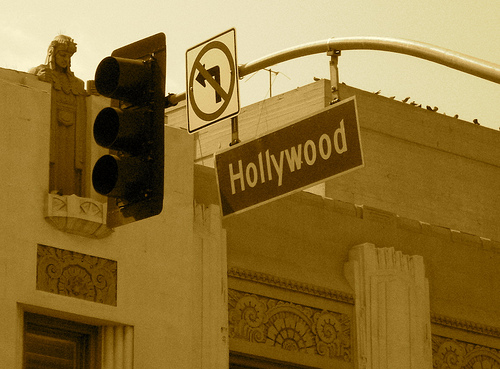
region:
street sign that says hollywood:
[187, 122, 449, 245]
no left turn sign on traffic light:
[160, 31, 287, 149]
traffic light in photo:
[74, 34, 234, 278]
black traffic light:
[79, 33, 264, 268]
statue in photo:
[39, 39, 111, 246]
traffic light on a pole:
[79, 46, 493, 204]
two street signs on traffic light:
[174, 42, 396, 242]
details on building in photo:
[200, 264, 467, 366]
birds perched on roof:
[306, 49, 497, 167]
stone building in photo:
[7, 67, 358, 364]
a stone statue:
[32, 22, 94, 212]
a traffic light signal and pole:
[87, 17, 497, 258]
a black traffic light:
[85, 25, 180, 240]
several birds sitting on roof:
[310, 65, 482, 128]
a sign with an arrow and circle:
[178, 22, 249, 135]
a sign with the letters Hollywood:
[209, 93, 370, 229]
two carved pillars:
[182, 189, 462, 367]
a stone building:
[0, 64, 497, 366]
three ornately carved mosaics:
[22, 225, 497, 367]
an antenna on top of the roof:
[243, 57, 292, 103]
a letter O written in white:
[245, 160, 257, 188]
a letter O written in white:
[301, 137, 317, 162]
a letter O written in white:
[318, 131, 333, 165]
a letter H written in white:
[224, 157, 246, 194]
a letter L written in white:
[256, 151, 265, 184]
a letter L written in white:
[263, 145, 273, 182]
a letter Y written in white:
[270, 147, 287, 184]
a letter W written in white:
[283, 142, 303, 170]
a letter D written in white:
[331, 115, 350, 152]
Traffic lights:
[91, 50, 146, 199]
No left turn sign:
[185, 26, 241, 133]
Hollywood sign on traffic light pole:
[206, 92, 361, 217]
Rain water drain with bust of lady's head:
[25, 31, 90, 226]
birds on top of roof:
[335, 66, 485, 126]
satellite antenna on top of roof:
[250, 65, 285, 95]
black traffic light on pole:
[91, 28, 165, 231]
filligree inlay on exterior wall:
[34, 239, 121, 307]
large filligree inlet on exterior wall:
[225, 255, 360, 364]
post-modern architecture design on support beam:
[344, 231, 437, 366]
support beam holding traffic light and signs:
[91, 26, 498, 231]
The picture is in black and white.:
[38, 18, 479, 323]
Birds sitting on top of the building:
[368, 76, 496, 124]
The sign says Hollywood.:
[213, 128, 365, 188]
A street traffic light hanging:
[99, 32, 186, 239]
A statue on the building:
[36, 38, 92, 203]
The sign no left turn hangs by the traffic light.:
[173, 38, 253, 120]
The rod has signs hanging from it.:
[245, 43, 493, 92]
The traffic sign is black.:
[90, 31, 177, 231]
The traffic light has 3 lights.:
[80, 52, 142, 202]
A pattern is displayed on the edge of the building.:
[236, 272, 351, 341]